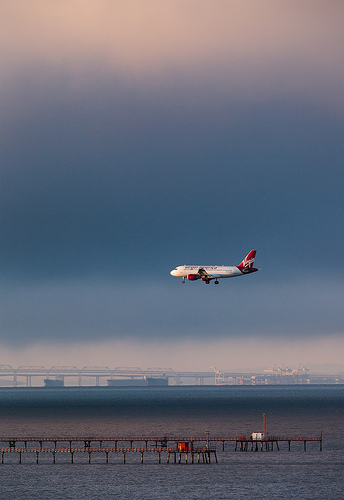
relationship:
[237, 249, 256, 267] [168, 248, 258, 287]
wing on jet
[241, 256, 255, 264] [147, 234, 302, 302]
stripe on plane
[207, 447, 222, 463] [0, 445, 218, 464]
post on dock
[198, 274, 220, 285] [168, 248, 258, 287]
landing wheels are on jet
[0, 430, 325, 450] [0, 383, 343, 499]
docks in ocean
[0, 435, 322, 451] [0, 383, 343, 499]
dock near in ocean